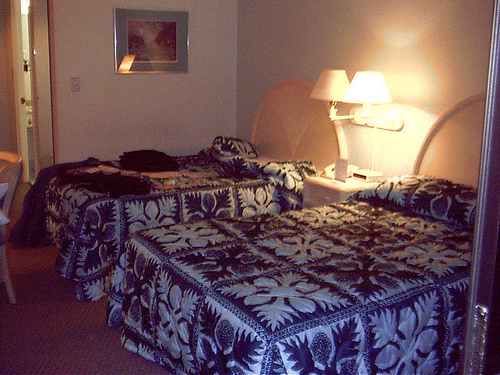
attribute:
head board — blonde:
[412, 92, 487, 189]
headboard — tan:
[247, 79, 347, 187]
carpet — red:
[1, 181, 193, 374]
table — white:
[298, 169, 378, 204]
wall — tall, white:
[49, 7, 234, 164]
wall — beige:
[66, 74, 293, 144]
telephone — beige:
[317, 158, 362, 183]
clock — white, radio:
[353, 170, 382, 182]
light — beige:
[304, 55, 427, 197]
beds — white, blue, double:
[7, 77, 487, 373]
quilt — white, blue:
[186, 243, 396, 338]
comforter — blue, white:
[46, 104, 461, 374]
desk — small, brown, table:
[281, 149, 387, 204]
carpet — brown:
[59, 292, 95, 374]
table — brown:
[289, 163, 384, 216]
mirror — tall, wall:
[29, 0, 56, 185]